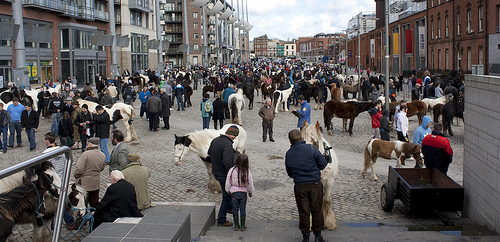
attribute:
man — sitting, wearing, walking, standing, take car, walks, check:
[70, 163, 163, 232]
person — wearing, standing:
[279, 93, 324, 132]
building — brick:
[157, 7, 195, 58]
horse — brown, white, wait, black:
[171, 110, 260, 179]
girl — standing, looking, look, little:
[221, 144, 258, 224]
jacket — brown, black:
[118, 156, 160, 199]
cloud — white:
[281, 6, 318, 31]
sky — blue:
[259, 8, 310, 47]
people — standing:
[226, 38, 336, 112]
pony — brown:
[342, 114, 431, 181]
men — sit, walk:
[77, 141, 187, 233]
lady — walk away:
[63, 104, 102, 158]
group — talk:
[43, 72, 124, 143]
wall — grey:
[456, 98, 493, 176]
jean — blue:
[224, 188, 259, 227]